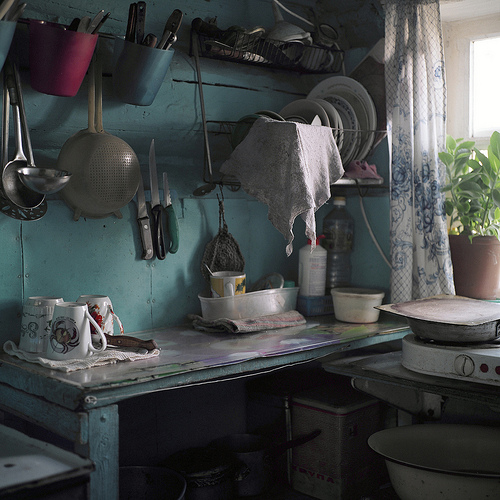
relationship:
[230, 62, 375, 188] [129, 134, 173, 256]
plates beside knifes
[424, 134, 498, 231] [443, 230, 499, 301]
plant in pot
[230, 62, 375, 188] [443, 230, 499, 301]
plates in pot